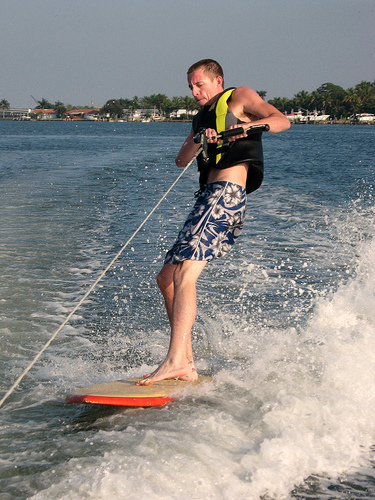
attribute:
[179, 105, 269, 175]
vest — black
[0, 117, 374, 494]
water — blue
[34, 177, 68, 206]
water — blue, ocean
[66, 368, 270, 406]
surfboard — yellow, orange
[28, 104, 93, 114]
roofs — red